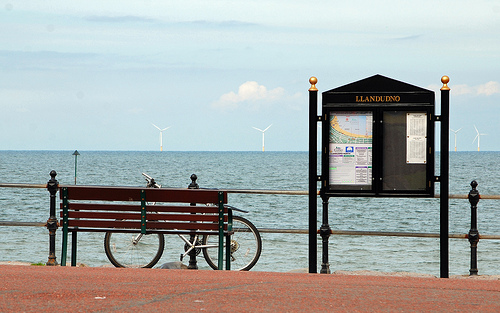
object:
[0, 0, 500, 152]
sky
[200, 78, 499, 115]
cloud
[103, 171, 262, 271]
bike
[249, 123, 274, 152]
windmill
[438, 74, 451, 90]
knob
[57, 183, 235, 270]
bench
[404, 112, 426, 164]
sign